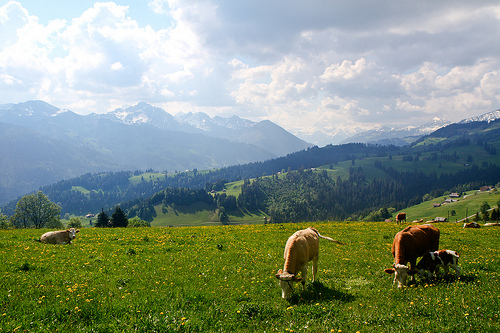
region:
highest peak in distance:
[9, 89, 71, 117]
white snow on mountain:
[107, 108, 149, 125]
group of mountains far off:
[183, 106, 280, 139]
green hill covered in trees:
[25, 171, 185, 213]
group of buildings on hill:
[431, 183, 497, 206]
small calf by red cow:
[406, 246, 466, 280]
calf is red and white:
[403, 249, 463, 279]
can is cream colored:
[255, 212, 347, 302]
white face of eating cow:
[275, 273, 299, 298]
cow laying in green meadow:
[34, 220, 88, 249]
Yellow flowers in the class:
[36, 278, 120, 313]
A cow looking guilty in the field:
[31, 220, 91, 246]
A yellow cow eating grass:
[271, 223, 342, 302]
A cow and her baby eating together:
[375, 222, 470, 292]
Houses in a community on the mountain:
[427, 171, 495, 209]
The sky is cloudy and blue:
[26, 25, 371, 94]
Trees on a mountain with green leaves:
[138, 183, 348, 205]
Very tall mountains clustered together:
[18, 98, 284, 155]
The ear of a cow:
[61, 224, 72, 237]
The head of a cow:
[274, 268, 298, 299]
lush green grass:
[9, 220, 493, 326]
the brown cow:
[388, 223, 440, 282]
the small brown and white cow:
[416, 249, 463, 279]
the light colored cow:
[276, 227, 344, 302]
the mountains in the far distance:
[3, 98, 307, 170]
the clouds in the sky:
[8, 3, 498, 128]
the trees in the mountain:
[31, 126, 415, 216]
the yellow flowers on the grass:
[84, 223, 274, 309]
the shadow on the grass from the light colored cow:
[293, 280, 356, 310]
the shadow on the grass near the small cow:
[421, 273, 472, 287]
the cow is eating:
[264, 219, 344, 318]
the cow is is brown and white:
[401, 239, 476, 277]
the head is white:
[391, 261, 411, 293]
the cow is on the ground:
[32, 213, 108, 263]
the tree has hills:
[269, 128, 450, 206]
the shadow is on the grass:
[309, 256, 353, 317]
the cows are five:
[34, 200, 481, 317]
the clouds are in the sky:
[227, 46, 444, 118]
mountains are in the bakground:
[128, 104, 358, 139]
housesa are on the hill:
[424, 182, 491, 210]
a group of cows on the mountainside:
[31, 197, 487, 322]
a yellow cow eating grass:
[265, 223, 346, 306]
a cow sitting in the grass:
[30, 226, 85, 246]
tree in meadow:
[95, 211, 132, 225]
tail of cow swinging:
[312, 225, 339, 242]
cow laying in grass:
[32, 230, 79, 242]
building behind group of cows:
[444, 192, 474, 200]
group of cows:
[387, 210, 479, 227]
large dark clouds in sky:
[104, 1, 491, 125]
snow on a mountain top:
[105, 106, 150, 124]